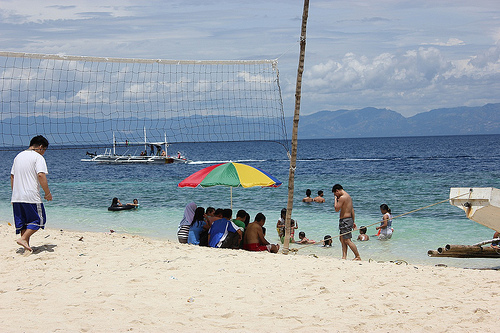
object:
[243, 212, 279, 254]
people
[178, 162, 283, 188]
umbrella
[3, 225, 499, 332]
sand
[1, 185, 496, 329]
beach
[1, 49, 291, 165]
net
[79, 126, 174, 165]
boat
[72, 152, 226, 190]
water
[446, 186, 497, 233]
boat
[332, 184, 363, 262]
people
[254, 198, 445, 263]
water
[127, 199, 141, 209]
people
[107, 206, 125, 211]
tubes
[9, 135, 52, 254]
man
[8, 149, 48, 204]
top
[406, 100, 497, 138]
mountains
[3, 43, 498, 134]
background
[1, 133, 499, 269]
ocean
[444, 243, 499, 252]
pipes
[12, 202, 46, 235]
shorts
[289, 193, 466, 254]
rope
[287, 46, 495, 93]
clouds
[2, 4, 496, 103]
sky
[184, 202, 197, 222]
towel